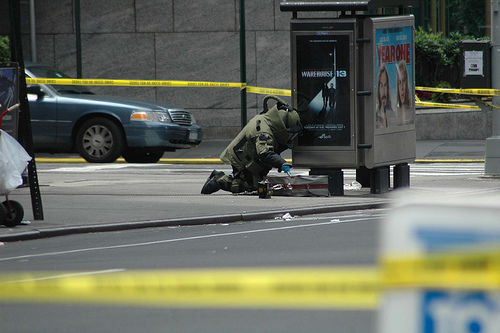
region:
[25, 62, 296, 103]
the ribbon is yellow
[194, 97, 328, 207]
man kneeling on the floor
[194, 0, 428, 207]
man on side a bus stop cabin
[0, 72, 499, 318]
yellow ribbon to cercle an area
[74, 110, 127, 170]
front wheel of car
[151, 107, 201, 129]
front lights on car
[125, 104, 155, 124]
orange signaling light on car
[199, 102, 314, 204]
man wears green clothes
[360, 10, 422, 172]
a board with advertisment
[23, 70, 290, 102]
black letters on yellow ribbon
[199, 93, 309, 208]
person in a bomb suit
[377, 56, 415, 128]
people on the sign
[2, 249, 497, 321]
yellow police tape in the forefront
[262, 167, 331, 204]
package on the ground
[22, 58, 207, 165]
car parked on the street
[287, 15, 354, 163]
sign on the board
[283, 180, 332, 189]
red line on package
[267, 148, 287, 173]
glove on the hand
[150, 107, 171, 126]
headlight on the car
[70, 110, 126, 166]
tire on the car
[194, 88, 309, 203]
man down on knees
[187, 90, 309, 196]
man dressed in all green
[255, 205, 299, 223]
litter on street near curb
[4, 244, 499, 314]
caution tape in foreground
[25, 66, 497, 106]
caution tape in background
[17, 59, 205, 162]
front end of blue green car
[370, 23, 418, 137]
poster ad for Year One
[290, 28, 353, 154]
poster ad for Warehouse 13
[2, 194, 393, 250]
concrete curb beside street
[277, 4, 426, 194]
display kiosk for ads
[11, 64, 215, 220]
a part of car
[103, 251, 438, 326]
a yellow line in the road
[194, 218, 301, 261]
a white line in the road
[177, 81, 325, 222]
a man sitting in the road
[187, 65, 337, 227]
a man sitting near the vehicle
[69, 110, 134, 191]
tire of the car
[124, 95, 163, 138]
light indicator of car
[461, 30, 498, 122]
a board in the building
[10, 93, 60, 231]
a iron rod in road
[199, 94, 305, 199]
A man diffusing a bomb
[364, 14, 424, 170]
movie poster on display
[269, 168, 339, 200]
a bomb in a bag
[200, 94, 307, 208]
A man wearing protective gear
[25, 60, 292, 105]
Police tape across an area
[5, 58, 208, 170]
Car parked on side of street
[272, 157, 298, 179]
Bomb diffusing tools being used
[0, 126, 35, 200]
white garbage bag hanging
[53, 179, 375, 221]
sidewalk corner near street intersection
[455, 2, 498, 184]
utility pole near street intersection